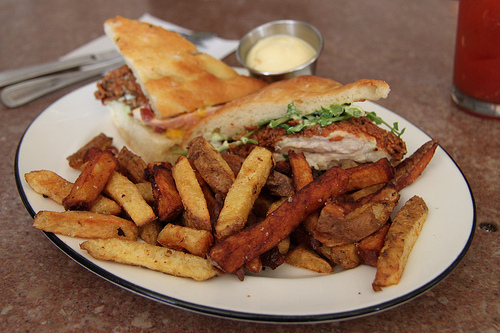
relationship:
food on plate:
[26, 14, 444, 293] [16, 57, 477, 323]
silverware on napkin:
[2, 33, 219, 107] [61, 11, 241, 76]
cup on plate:
[217, 26, 328, 93] [84, 109, 461, 293]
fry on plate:
[376, 196, 421, 301] [16, 57, 477, 323]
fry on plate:
[388, 136, 448, 193] [16, 57, 477, 323]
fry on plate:
[165, 148, 215, 230] [16, 57, 477, 323]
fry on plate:
[78, 232, 226, 282] [16, 57, 477, 323]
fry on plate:
[23, 200, 148, 241] [16, 57, 477, 323]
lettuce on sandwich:
[266, 97, 406, 139] [78, 9, 411, 170]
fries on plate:
[24, 127, 444, 298] [429, 186, 464, 223]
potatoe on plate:
[171, 155, 213, 232] [429, 186, 464, 223]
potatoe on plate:
[206, 162, 349, 271] [16, 57, 477, 323]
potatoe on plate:
[370, 193, 431, 287] [16, 57, 477, 323]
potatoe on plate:
[78, 235, 217, 281] [16, 57, 477, 323]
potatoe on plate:
[171, 155, 209, 229] [16, 57, 477, 323]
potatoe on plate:
[32, 205, 137, 237] [16, 57, 477, 323]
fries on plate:
[24, 127, 444, 298] [16, 57, 477, 323]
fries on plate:
[24, 127, 444, 298] [42, 24, 482, 331]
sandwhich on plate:
[214, 75, 402, 162] [7, 92, 94, 168]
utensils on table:
[3, 11, 210, 111] [0, 5, 494, 329]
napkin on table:
[62, 2, 247, 83] [0, 5, 494, 329]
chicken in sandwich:
[240, 116, 407, 173] [180, 74, 404, 174]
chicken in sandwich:
[95, 65, 146, 124] [99, 14, 264, 151]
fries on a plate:
[18, 126, 443, 297] [16, 57, 477, 323]